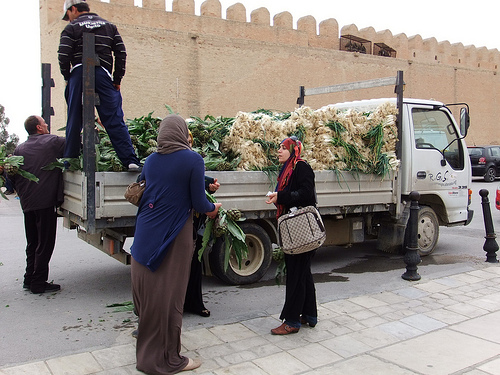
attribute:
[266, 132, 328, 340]
woman — standing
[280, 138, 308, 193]
head scarf — multi color, red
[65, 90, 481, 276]
truck — full, parked, white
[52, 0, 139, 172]
man — standing, blue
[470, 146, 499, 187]
car — driving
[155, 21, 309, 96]
wall — brick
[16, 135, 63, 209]
jacket — gray, dark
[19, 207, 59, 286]
pants — black, dark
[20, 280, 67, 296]
shoes — dark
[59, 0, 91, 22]
baseball cap — white, gray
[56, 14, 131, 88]
jacket — black, white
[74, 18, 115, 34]
lettering — white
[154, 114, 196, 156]
scarf — brown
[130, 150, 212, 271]
sweater — blue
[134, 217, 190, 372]
skirt — brown, gray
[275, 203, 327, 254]
bag — carryall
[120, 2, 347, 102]
building — beige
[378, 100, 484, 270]
front — white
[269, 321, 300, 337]
shoes — brown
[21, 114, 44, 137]
hair — dark, short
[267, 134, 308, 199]
scarf — red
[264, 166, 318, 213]
arm — black